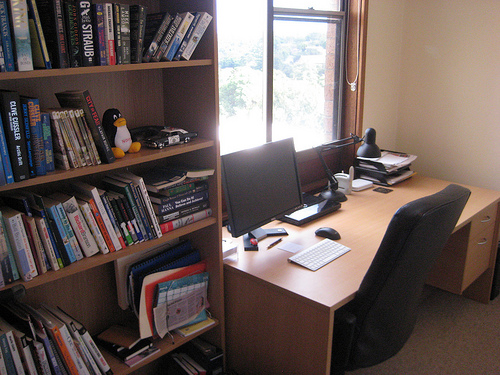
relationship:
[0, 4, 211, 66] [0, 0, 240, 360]
books on shelf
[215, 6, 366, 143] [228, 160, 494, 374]
window above desk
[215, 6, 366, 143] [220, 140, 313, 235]
window above monitor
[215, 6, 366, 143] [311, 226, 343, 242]
window above mouse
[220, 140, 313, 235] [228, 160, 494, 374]
monitor on desk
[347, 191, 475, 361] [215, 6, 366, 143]
chair below window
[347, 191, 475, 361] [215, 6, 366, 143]
chair under window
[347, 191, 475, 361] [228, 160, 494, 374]
chair under desk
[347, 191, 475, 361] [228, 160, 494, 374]
chair below desk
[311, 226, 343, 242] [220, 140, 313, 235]
mouse near monitor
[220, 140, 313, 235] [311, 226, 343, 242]
monitor near mouse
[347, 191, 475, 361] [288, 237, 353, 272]
chair near keyboard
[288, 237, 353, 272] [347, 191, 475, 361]
keyboard near chair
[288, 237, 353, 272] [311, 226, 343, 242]
keyboard near mouse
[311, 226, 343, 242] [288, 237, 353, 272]
mouse near keyboard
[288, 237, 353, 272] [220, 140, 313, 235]
keyboard near monitor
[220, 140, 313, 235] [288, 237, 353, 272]
monitor near keyboard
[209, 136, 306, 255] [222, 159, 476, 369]
computer monitor on desk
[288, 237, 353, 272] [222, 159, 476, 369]
keyboard on desk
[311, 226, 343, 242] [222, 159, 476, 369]
mouse on desk